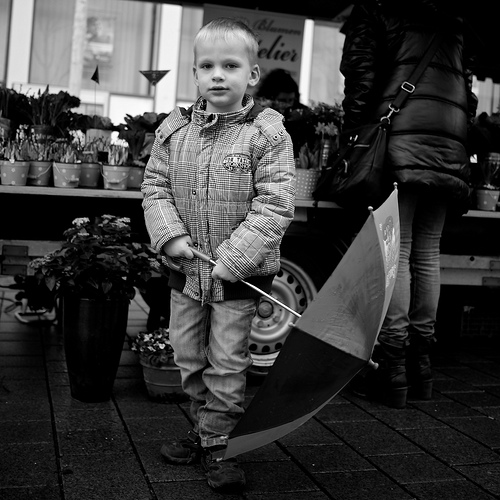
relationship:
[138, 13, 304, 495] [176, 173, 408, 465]
child holding umbrella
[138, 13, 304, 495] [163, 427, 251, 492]
child has shoes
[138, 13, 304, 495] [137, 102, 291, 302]
child has jacket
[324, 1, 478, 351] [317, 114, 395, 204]
woman has handbag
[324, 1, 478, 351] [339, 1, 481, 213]
woman has jacket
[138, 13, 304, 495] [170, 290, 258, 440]
child has jeans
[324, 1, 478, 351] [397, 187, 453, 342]
woman has jeans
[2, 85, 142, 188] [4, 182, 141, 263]
plants are on cart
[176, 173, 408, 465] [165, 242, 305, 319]
umbrella has handle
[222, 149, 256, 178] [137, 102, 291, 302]
insignia on jacket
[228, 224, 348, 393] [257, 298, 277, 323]
wheel has lug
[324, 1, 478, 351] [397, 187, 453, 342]
woman wears jeans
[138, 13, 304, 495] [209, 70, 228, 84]
child has nose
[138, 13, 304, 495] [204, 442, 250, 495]
child has shoe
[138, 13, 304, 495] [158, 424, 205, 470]
child has shoe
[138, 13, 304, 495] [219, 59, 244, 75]
child has eye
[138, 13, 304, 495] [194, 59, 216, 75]
child has eye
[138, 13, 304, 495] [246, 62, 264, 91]
child has ear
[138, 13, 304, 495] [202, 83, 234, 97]
child has mouth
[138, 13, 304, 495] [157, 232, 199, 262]
child has hand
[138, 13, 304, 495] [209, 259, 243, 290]
child has hand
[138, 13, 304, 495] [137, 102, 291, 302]
child wearing jacket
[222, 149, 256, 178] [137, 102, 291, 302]
patch on jacket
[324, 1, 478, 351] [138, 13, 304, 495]
woman behind child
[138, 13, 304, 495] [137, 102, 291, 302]
child in jacket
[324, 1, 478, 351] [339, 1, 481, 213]
woman in jacket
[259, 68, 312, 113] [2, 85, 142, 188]
lady selling flowers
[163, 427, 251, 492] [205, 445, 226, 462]
sneakers have velcro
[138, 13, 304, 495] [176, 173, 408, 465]
child has umbrella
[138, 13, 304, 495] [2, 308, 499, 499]
child standing on sidewalk